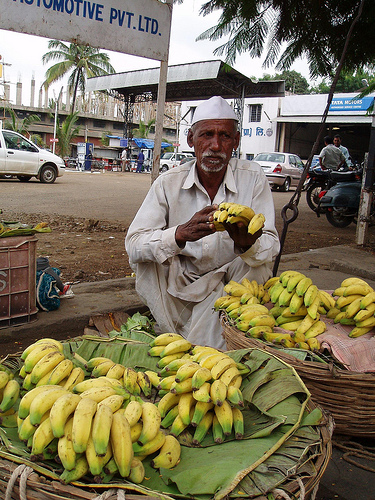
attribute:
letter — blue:
[148, 16, 160, 37]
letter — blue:
[124, 9, 133, 28]